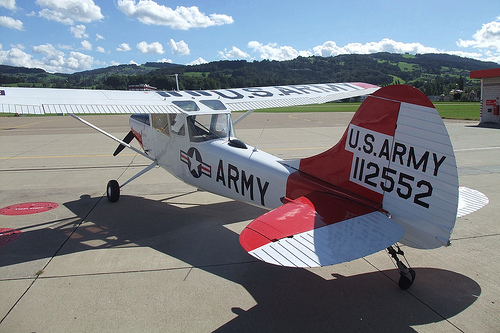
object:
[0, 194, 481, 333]
shadow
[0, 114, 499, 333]
ground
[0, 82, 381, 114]
wing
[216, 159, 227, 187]
letters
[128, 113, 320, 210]
fuselage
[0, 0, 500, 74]
sky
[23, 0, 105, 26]
cloud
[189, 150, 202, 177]
star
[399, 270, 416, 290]
wheel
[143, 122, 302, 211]
body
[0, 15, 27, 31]
cloud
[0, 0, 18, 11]
cloud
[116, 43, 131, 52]
cloud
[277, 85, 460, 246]
tail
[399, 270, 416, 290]
tail wheel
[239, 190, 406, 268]
pannel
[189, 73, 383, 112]
right wing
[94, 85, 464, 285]
aircraft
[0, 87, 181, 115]
left wing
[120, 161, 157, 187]
landing gear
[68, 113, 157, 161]
strut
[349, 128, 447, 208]
writing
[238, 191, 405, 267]
wing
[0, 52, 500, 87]
moutains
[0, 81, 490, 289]
plane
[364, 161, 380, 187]
lettering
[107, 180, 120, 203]
wheel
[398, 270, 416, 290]
tire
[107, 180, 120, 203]
tire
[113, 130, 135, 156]
propeller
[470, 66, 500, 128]
building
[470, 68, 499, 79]
roof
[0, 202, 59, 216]
manhole cover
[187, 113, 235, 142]
window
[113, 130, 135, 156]
propeller blade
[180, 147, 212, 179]
logo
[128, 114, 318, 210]
side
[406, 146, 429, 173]
letters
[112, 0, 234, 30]
clouds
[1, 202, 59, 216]
circle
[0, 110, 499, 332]
pavement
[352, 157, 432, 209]
112552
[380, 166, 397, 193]
letters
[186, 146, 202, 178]
circle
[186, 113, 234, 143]
windshield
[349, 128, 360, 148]
letter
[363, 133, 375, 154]
letter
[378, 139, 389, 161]
letter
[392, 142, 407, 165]
letter